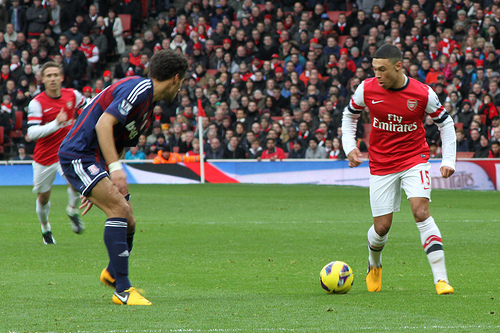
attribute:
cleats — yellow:
[97, 271, 152, 310]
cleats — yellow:
[365, 261, 454, 297]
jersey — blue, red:
[46, 72, 156, 183]